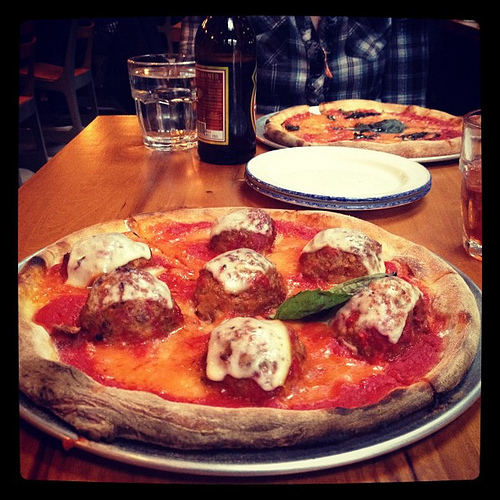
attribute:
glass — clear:
[136, 43, 187, 152]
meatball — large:
[208, 327, 310, 403]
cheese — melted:
[225, 327, 268, 370]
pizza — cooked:
[64, 212, 462, 430]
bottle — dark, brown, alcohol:
[200, 22, 258, 163]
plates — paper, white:
[233, 136, 436, 213]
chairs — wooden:
[26, 41, 110, 126]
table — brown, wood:
[82, 121, 282, 223]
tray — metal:
[251, 111, 302, 149]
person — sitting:
[230, 19, 484, 105]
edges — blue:
[271, 185, 329, 206]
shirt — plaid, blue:
[194, 28, 443, 88]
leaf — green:
[282, 293, 331, 322]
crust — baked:
[51, 382, 281, 452]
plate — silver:
[256, 115, 277, 153]